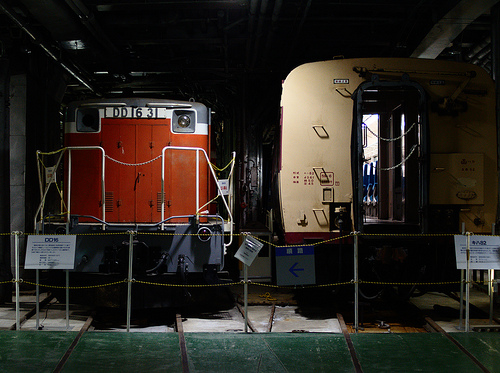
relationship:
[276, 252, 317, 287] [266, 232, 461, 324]
blue arrow on gray background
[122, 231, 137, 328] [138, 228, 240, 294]
metal posts hooked to chains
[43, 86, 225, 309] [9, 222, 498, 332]
train behind fence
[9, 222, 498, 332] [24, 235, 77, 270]
fence with shaped sign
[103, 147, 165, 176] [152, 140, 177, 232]
chain between post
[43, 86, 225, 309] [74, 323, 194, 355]
train on tracks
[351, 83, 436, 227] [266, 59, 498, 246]
doorway to train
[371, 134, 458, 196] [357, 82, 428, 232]
chain blocking doorway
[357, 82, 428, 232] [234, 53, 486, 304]
doorway on train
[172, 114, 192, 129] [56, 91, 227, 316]
light on train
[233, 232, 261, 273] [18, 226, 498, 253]
paper on chain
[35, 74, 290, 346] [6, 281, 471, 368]
train on tracks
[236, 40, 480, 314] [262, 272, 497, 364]
train on track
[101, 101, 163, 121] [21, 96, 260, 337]
letters are on train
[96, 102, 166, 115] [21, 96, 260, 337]
number are on train